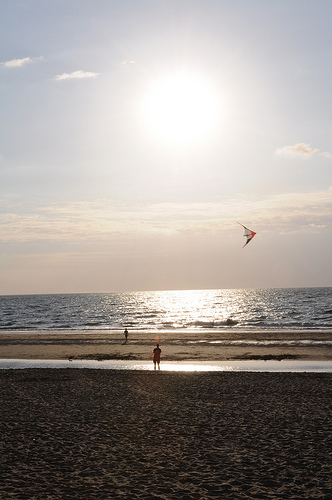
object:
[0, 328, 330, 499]
beach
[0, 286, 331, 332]
sea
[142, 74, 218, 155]
sun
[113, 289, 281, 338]
sunset reflecting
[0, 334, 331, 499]
sand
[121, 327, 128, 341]
child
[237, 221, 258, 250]
kite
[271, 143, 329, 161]
cloud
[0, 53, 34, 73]
cloud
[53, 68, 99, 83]
cloud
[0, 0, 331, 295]
sky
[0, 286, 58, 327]
waves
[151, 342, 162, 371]
man